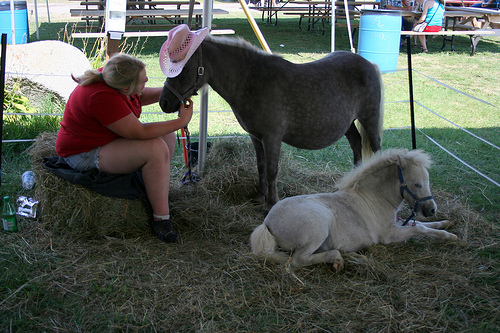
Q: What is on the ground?
A: Hay.